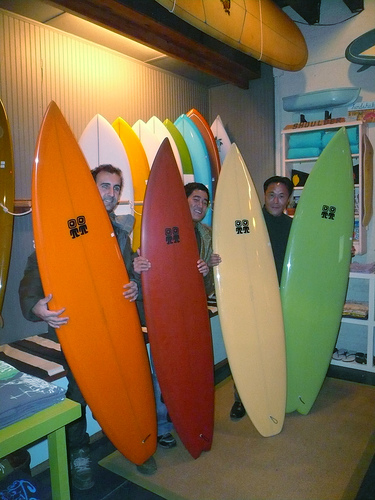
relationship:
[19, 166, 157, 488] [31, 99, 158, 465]
person holding surfboard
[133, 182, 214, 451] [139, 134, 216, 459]
person holding surfboard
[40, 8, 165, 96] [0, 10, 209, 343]
light shining on wall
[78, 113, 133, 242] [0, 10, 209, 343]
surfboard against wall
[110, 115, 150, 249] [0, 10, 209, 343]
surfboard against wall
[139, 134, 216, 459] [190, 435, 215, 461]
surfboard has tail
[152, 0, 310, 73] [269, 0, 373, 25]
surfboard hanging from ceiling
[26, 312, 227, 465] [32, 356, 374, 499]
cabinet sitting on floor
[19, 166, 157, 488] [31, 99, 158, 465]
person carrying surfboard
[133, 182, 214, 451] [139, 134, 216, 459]
person carrying surfboard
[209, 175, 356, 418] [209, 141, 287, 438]
person carrying surfboard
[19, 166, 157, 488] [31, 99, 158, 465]
person standing with surfboard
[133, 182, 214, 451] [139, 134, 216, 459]
person standing with surfboard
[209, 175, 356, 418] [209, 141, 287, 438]
person standing with surfboard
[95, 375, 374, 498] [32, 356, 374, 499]
mat laying on floor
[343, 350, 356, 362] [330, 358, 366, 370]
shoe sitting on shelf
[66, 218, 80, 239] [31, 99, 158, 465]
caricature on top of surfboard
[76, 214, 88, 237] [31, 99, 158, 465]
caricature on top of surfboard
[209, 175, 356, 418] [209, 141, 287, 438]
person holding surfboard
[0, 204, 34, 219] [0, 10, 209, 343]
cord hanging on wall